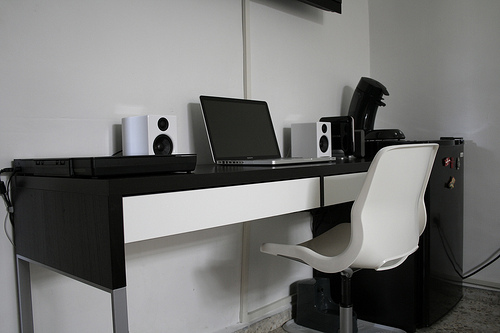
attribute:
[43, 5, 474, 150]
wall — white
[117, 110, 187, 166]
stereo speaker — small, white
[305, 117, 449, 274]
stool — white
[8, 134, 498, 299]
table — black, white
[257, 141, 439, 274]
stool — white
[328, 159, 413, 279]
stool — white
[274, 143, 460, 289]
stool — white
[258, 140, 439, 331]
stool — white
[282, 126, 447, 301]
stool — white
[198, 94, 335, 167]
laptop — off, open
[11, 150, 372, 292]
table — white, black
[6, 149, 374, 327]
desk — small, metal